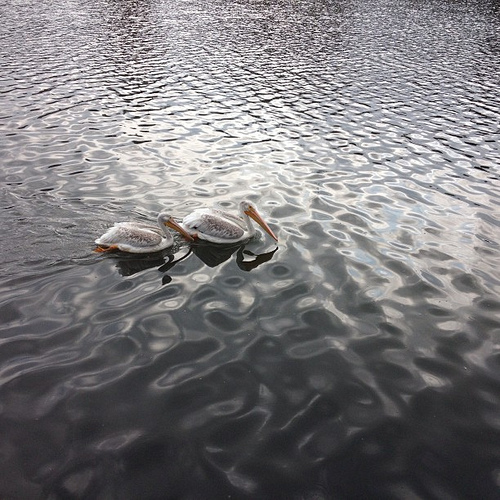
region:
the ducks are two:
[87, 184, 297, 272]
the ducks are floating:
[84, 182, 279, 281]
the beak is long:
[161, 214, 197, 246]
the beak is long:
[250, 212, 280, 247]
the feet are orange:
[92, 237, 119, 254]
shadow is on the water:
[235, 242, 275, 273]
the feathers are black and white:
[186, 206, 252, 248]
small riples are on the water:
[123, 292, 333, 402]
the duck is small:
[95, 209, 191, 263]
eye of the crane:
[248, 204, 253, 210]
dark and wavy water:
[113, 300, 379, 421]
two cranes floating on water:
[97, 197, 282, 264]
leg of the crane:
[95, 243, 117, 253]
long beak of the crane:
[248, 209, 280, 241]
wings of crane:
[189, 213, 241, 238]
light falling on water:
[151, 110, 296, 168]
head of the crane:
[159, 213, 171, 224]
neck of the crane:
[243, 215, 253, 237]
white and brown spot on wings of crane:
[191, 218, 242, 235]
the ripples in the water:
[106, 288, 443, 448]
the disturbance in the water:
[0, 215, 91, 260]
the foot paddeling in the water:
[87, 236, 107, 260]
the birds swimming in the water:
[88, 198, 285, 260]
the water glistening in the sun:
[22, 3, 488, 110]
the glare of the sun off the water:
[95, 110, 471, 211]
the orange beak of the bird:
[248, 208, 281, 242]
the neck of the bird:
[240, 209, 256, 241]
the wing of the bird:
[95, 223, 162, 248]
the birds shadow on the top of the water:
[116, 249, 280, 310]